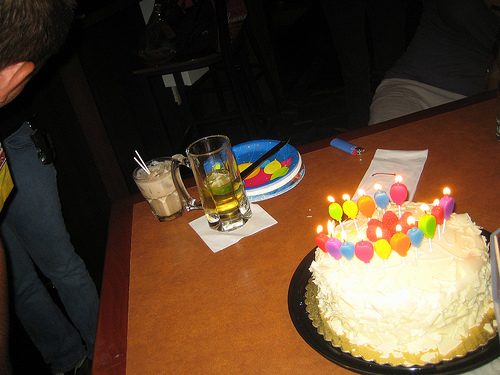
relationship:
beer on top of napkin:
[170, 134, 252, 231] [187, 202, 279, 254]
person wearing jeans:
[0, 1, 99, 373] [2, 121, 102, 371]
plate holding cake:
[272, 277, 304, 331] [349, 255, 452, 319]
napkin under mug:
[187, 204, 278, 253] [165, 115, 257, 247]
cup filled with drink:
[133, 156, 183, 222] [135, 161, 183, 217]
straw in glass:
[126, 145, 163, 182] [154, 190, 174, 211]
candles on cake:
[315, 181, 455, 264] [371, 308, 467, 328]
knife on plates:
[238, 136, 290, 177] [230, 135, 305, 204]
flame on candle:
[313, 220, 325, 236] [314, 182, 455, 259]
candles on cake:
[315, 192, 432, 247] [332, 281, 460, 316]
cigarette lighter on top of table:
[330, 137, 365, 156] [95, 84, 497, 374]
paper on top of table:
[347, 146, 433, 226] [95, 84, 497, 374]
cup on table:
[133, 156, 183, 222] [95, 84, 499, 374]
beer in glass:
[199, 169, 248, 233] [170, 135, 251, 233]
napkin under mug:
[187, 202, 279, 254] [169, 133, 251, 233]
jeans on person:
[0, 121, 100, 372] [0, 1, 99, 373]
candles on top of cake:
[315, 181, 455, 264] [310, 192, 494, 359]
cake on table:
[309, 178, 496, 354] [95, 84, 497, 374]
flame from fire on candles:
[312, 173, 453, 243] [312, 182, 456, 265]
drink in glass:
[132, 159, 184, 220] [172, 131, 251, 229]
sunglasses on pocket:
[27, 116, 57, 164] [10, 124, 40, 162]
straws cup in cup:
[125, 150, 151, 180] [134, 164, 183, 218]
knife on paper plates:
[234, 136, 291, 182] [203, 139, 306, 203]